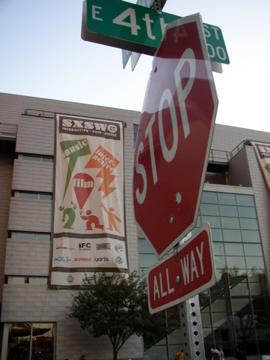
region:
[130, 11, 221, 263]
red and white stop sign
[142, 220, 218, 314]
red and white sign that says all way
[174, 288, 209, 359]
metal pole holding up sign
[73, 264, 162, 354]
green tree behind building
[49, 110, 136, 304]
large sign hanging on the building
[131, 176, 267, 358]
large grouping of windows on the building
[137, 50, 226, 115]
sky reflecting on the stop sign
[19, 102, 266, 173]
railing at the top of the building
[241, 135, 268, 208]
part of another poster hanging on the building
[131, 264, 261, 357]
objects reflecting in the windows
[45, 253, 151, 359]
a tree in front of the building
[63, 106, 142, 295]
a giant ad on the building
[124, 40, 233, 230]
a red STOP sign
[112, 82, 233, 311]
a red STOP sign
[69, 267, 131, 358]
a tree by the wall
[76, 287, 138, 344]
A tree in the photo.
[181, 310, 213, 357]
A metal pole in the photo.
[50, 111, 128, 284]
A banner in the photo.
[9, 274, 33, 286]
Windows in the photo.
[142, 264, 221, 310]
ALL WAY sign in the photo.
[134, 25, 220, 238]
STOP sign in the photo.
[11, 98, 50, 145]
A building in the picture.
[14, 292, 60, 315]
A concrete wall in the photo.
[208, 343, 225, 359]
People in the photo.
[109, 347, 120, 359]
Tree trunk in the photo.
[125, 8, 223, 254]
a red stop sign.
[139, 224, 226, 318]
A sign under a red stop sign.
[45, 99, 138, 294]
A banner on a building.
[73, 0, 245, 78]
a green street sign.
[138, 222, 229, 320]
A all way sign.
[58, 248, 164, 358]
A tree near a building.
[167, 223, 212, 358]
A metal pole.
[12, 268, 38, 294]
A hole in a building.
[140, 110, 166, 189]
A t on a stop sign.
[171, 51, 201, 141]
A large white p.